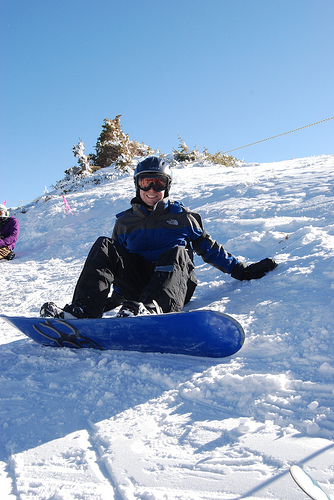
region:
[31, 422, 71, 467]
Snow covering the ground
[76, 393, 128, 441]
Snow covering the ground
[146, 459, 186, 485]
Snow covering the ground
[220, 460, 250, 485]
Snow covering the ground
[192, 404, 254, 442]
Snow covering the ground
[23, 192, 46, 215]
PAtch of snow covering the ground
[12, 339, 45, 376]
PAtch of snow covering the ground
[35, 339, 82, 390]
PAtch of snow covering the ground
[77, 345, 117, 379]
PAtch of snow covering the ground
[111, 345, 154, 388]
PAtch of snow covering the ground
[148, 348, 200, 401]
PAtch of snow covering the ground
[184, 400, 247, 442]
PAtch of snow covering the ground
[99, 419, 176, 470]
PAtch of snow covering the ground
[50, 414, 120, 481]
PAtch of snow covering the ground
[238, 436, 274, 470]
PAtch of snow covering the ground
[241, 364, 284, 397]
a chunk of snow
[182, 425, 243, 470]
the snow is white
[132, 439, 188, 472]
the snow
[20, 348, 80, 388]
a shadow on the snow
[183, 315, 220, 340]
bottom of the snowboard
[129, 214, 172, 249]
the jacket is brown and black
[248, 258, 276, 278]
the glove is black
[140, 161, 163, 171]
a helmet the man is wearing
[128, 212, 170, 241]
a jacket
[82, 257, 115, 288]
man is wearing black pants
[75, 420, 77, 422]
man cutting birthday cake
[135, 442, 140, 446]
man cutting birthday cake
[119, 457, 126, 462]
man cutting birthday cake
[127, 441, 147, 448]
man cutting birthday cake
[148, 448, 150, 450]
man cutting birthday cake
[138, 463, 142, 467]
man cutting birthday cake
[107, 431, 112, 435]
man cutting birthday cake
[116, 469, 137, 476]
man cutting birthday cake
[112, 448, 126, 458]
man cutting birthday cake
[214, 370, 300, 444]
the snow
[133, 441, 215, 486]
the snow is white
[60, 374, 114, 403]
a shadow on the snow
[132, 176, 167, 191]
the man is wearing snow goggles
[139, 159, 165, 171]
a helmet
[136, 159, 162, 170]
the helmet is black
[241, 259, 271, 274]
the person is wearing gloves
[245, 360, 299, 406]
chunks of snow that is white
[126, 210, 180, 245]
a black and blue sweater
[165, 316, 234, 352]
the bottom of the snowboard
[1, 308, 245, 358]
blue and black snowboard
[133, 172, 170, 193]
black rim goggles with dark lens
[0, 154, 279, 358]
man falling down on a snowboard